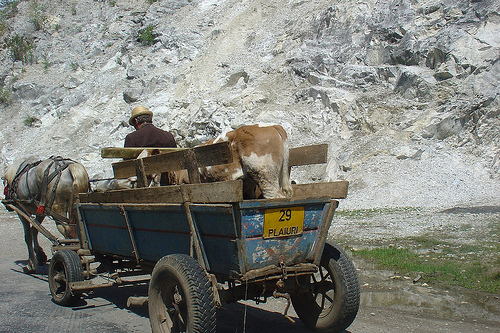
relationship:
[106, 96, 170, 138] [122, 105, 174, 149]
hat on man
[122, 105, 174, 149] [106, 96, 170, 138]
man wearing hat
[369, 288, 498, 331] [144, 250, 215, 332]
dirt in wheel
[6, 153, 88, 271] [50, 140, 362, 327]
horse pulling carriage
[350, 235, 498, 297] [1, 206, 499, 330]
grass in road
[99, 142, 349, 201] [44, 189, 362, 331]
fence around cart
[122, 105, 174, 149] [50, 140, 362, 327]
man driving carriage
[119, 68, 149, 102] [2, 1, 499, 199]
rocks on hillside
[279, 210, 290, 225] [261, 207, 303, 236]
29 on license plate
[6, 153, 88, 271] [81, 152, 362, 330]
horse pulling wagon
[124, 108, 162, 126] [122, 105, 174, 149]
hat worn by man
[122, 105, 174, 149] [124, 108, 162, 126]
man wears hat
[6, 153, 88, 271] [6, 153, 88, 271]
horse on horse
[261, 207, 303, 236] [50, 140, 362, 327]
license plate on carriage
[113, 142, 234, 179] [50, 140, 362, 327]
wood plank on carriage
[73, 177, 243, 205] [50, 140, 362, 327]
wood plank on carriage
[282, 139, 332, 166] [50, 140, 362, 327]
wood plank on carriage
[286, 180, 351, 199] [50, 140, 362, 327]
wood plank on carriage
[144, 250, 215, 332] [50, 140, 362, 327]
wheel on carriage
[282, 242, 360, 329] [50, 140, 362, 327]
wheel on carriage